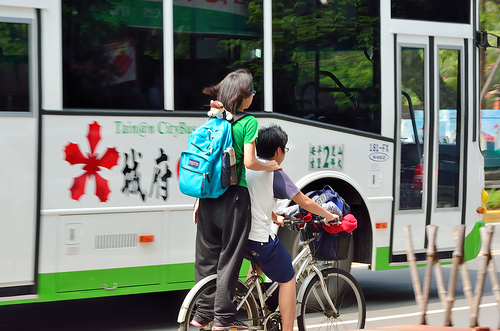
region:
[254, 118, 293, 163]
the head of a man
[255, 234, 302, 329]
the leg of a man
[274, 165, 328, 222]
the arm of a man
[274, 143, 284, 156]
the ear of a man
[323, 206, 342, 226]
the hand of a man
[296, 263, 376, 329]
the wheel of a bicycle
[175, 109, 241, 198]
a blue backpack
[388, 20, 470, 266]
the doors of a bus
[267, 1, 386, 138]
a window on the bus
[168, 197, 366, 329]
a white bicycle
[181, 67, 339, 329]
the kids on the back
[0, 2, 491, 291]
the big bus on the road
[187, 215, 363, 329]
the white bike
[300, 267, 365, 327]
the front wheel on the bike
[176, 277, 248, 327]
the back wheel on the bike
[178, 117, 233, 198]
the blue back pack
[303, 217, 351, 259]
the bike's basket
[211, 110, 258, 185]
the short sleeved green shirt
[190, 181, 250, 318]
the long black pants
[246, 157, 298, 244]
the boy's short sleeved shirt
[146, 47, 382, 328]
Two people on a bicycle.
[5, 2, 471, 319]
A bis driving down the street.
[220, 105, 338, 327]
The man is riding the bicycle.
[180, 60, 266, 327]
The woman is standing on the back of the bicycle.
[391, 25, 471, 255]
The front door on the bus.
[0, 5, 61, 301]
A back doog on the bus.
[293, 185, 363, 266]
The basket on the bicycle.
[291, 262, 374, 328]
The front wheel of the bicycle.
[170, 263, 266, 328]
The back wheel of the bicycle.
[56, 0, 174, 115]
A window on the bus.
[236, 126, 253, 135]
Girl wearing green shirt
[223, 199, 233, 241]
Girl wearing black sweats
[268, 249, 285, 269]
boy wearing blue shorts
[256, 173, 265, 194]
boy wearing white shirt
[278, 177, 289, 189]
purple sleeves on shirt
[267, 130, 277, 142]
boy has black hair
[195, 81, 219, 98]
girl has brown hair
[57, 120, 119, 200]
red symbol on bus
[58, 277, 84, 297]
green color on bus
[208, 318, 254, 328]
girl wearing multicolored sneakers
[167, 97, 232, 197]
a light blue backpack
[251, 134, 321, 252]
person riding a bike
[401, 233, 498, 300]
wooden sticks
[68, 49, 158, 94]
window of the bus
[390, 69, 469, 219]
the door of the bus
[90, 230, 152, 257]
vents on the bus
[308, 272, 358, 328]
front tire of the bike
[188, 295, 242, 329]
back tire of the bike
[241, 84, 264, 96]
person standing is wearing glasses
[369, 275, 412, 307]
the bus is on the street